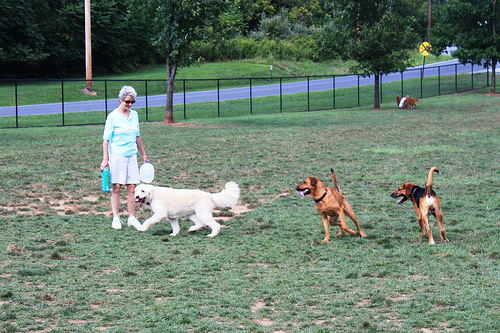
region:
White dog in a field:
[124, 185, 245, 240]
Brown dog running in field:
[297, 173, 368, 244]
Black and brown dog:
[391, 166, 461, 245]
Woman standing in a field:
[102, 85, 152, 231]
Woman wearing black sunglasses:
[120, 88, 135, 110]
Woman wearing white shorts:
[105, 150, 141, 185]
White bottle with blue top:
[140, 158, 155, 185]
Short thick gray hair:
[118, 84, 137, 104]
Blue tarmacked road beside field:
[1, 43, 493, 117]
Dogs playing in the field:
[133, 168, 453, 248]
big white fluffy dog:
[126, 174, 246, 244]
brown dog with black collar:
[290, 155, 371, 267]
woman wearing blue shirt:
[88, 71, 154, 239]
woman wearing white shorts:
[87, 65, 151, 235]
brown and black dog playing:
[387, 145, 447, 249]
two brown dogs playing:
[392, 85, 423, 123]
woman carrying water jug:
[83, 80, 169, 236]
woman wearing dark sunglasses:
[87, 74, 159, 233]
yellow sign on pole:
[415, 38, 436, 101]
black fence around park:
[20, 70, 494, 115]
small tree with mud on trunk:
[128, 0, 215, 127]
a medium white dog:
[132, 180, 239, 238]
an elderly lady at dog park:
[97, 87, 152, 228]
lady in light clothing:
[101, 88, 153, 230]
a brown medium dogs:
[297, 168, 365, 239]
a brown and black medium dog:
[394, 166, 446, 243]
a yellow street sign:
[417, 40, 433, 56]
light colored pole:
[82, 2, 95, 92]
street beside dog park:
[1, 55, 497, 120]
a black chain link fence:
[2, 58, 494, 126]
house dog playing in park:
[382, 154, 458, 256]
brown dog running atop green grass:
[263, 164, 370, 269]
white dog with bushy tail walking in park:
[123, 175, 257, 252]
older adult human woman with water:
[96, 78, 154, 250]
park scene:
[35, 38, 475, 320]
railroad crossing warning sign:
[410, 37, 447, 105]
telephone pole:
[62, 2, 103, 96]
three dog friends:
[108, 157, 463, 271]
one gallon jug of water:
[130, 157, 159, 185]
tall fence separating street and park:
[2, 45, 492, 145]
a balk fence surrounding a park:
[0, 58, 490, 128]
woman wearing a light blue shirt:
[103, 107, 138, 155]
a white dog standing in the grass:
[131, 181, 240, 236]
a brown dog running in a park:
[297, 165, 367, 241]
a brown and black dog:
[391, 167, 448, 246]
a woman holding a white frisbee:
[138, 157, 155, 185]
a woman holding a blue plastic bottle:
[101, 167, 111, 191]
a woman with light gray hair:
[116, 83, 138, 109]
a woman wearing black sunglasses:
[123, 94, 135, 106]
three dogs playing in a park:
[130, 166, 449, 246]